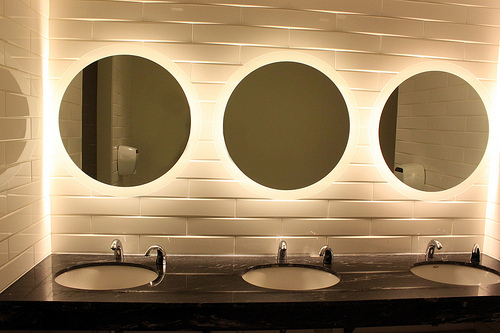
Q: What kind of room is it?
A: It is a bathroom.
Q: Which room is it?
A: It is a bathroom.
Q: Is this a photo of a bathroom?
A: Yes, it is showing a bathroom.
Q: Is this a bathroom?
A: Yes, it is a bathroom.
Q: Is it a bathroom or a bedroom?
A: It is a bathroom.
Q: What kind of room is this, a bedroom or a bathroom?
A: It is a bathroom.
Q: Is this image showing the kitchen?
A: No, the picture is showing the bathroom.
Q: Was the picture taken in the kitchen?
A: No, the picture was taken in the bathroom.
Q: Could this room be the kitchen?
A: No, it is the bathroom.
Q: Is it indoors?
A: Yes, it is indoors.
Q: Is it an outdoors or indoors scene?
A: It is indoors.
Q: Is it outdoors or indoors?
A: It is indoors.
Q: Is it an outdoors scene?
A: No, it is indoors.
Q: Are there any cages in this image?
A: No, there are no cages.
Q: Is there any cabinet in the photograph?
A: No, there are no cabinets.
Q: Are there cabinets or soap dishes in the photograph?
A: No, there are no cabinets or soap dishes.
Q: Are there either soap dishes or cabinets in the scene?
A: No, there are no cabinets or soap dishes.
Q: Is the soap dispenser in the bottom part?
A: Yes, the soap dispenser is in the bottom of the image.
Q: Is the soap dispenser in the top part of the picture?
A: No, the soap dispenser is in the bottom of the image.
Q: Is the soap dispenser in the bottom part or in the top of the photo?
A: The soap dispenser is in the bottom of the image.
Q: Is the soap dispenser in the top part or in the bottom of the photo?
A: The soap dispenser is in the bottom of the image.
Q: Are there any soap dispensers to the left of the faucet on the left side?
A: No, the soap dispenser is to the right of the faucet.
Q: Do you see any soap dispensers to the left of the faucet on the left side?
A: No, the soap dispenser is to the right of the faucet.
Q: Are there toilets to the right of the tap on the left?
A: No, there is a soap dispenser to the right of the faucet.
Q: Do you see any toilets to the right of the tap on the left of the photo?
A: No, there is a soap dispenser to the right of the faucet.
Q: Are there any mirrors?
A: Yes, there is a mirror.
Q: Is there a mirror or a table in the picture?
A: Yes, there is a mirror.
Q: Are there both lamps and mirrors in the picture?
A: No, there is a mirror but no lamps.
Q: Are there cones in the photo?
A: No, there are no cones.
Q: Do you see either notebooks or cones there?
A: No, there are no cones or notebooks.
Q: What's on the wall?
A: The mirror is on the wall.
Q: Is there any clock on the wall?
A: No, there is a mirror on the wall.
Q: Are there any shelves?
A: No, there are no shelves.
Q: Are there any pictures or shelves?
A: No, there are no shelves or pictures.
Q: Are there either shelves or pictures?
A: No, there are no shelves or pictures.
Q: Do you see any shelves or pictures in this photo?
A: No, there are no shelves or pictures.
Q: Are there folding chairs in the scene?
A: No, there are no folding chairs.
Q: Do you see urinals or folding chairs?
A: No, there are no folding chairs or urinals.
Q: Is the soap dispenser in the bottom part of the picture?
A: Yes, the soap dispenser is in the bottom of the image.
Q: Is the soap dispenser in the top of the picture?
A: No, the soap dispenser is in the bottom of the image.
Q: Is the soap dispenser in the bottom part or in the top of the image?
A: The soap dispenser is in the bottom of the image.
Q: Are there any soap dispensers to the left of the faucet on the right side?
A: Yes, there is a soap dispenser to the left of the tap.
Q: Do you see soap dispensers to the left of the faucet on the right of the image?
A: Yes, there is a soap dispenser to the left of the tap.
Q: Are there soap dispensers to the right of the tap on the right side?
A: No, the soap dispenser is to the left of the faucet.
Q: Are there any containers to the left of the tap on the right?
A: No, there is a soap dispenser to the left of the faucet.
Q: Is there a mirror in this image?
A: Yes, there is a mirror.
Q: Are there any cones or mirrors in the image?
A: Yes, there is a mirror.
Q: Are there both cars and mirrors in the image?
A: No, there is a mirror but no cars.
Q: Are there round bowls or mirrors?
A: Yes, there is a round mirror.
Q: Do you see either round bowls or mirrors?
A: Yes, there is a round mirror.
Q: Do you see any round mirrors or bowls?
A: Yes, there is a round mirror.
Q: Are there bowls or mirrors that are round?
A: Yes, the mirror is round.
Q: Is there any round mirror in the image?
A: Yes, there is a round mirror.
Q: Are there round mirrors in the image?
A: Yes, there is a round mirror.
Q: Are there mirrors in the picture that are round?
A: Yes, there is a mirror that is round.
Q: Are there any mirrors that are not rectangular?
A: Yes, there is a round mirror.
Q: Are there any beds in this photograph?
A: No, there are no beds.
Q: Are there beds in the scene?
A: No, there are no beds.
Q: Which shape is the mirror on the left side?
A: The mirror is round.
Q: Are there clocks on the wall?
A: No, there is a mirror on the wall.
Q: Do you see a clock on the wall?
A: No, there is a mirror on the wall.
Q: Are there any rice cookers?
A: No, there are no rice cookers.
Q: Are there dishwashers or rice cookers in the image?
A: No, there are no rice cookers or dishwashers.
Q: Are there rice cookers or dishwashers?
A: No, there are no rice cookers or dishwashers.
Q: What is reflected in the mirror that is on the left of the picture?
A: The hand dryer is reflected in the mirror.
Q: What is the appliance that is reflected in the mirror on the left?
A: The appliance is a hand dryer.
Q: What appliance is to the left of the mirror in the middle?
A: The appliance is a hand dryer.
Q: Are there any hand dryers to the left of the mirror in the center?
A: Yes, there is a hand dryer to the left of the mirror.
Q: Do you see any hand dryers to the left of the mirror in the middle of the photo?
A: Yes, there is a hand dryer to the left of the mirror.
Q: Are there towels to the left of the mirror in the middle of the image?
A: No, there is a hand dryer to the left of the mirror.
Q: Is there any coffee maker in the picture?
A: No, there are no coffee makers.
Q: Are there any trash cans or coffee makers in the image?
A: No, there are no coffee makers or trash cans.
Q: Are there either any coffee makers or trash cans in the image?
A: No, there are no coffee makers or trash cans.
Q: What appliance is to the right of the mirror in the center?
A: The appliance is a hand dryer.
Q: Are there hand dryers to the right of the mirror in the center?
A: Yes, there is a hand dryer to the right of the mirror.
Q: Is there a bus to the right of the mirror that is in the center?
A: No, there is a hand dryer to the right of the mirror.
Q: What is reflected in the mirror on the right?
A: The hand dryer is reflected in the mirror.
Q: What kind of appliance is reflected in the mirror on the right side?
A: The appliance is a hand dryer.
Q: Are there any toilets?
A: No, there are no toilets.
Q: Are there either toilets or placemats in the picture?
A: No, there are no toilets or placemats.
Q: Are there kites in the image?
A: No, there are no kites.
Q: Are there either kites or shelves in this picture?
A: No, there are no kites or shelves.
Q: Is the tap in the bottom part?
A: Yes, the tap is in the bottom of the image.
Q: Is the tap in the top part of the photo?
A: No, the tap is in the bottom of the image.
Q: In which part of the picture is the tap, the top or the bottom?
A: The tap is in the bottom of the image.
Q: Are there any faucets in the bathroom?
A: Yes, there is a faucet in the bathroom.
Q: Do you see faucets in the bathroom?
A: Yes, there is a faucet in the bathroom.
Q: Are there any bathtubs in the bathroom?
A: No, there is a faucet in the bathroom.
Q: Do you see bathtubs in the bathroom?
A: No, there is a faucet in the bathroom.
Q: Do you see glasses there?
A: No, there are no glasses.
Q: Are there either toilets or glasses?
A: No, there are no glasses or toilets.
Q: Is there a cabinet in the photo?
A: No, there are no cabinets.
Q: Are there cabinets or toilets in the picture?
A: No, there are no cabinets or toilets.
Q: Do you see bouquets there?
A: No, there are no bouquets.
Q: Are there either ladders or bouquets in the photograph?
A: No, there are no bouquets or ladders.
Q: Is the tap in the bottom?
A: Yes, the tap is in the bottom of the image.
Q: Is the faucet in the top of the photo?
A: No, the faucet is in the bottom of the image.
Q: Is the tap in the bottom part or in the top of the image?
A: The tap is in the bottom of the image.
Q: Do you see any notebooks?
A: No, there are no notebooks.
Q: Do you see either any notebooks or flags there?
A: No, there are no notebooks or flags.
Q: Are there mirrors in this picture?
A: Yes, there is a mirror.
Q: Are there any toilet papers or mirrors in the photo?
A: Yes, there is a mirror.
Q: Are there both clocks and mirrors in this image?
A: No, there is a mirror but no clocks.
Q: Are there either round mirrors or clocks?
A: Yes, there is a round mirror.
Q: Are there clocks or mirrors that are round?
A: Yes, the mirror is round.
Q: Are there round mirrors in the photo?
A: Yes, there is a round mirror.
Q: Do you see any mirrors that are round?
A: Yes, there is a round mirror.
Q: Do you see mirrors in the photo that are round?
A: Yes, there is a mirror that is round.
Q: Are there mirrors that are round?
A: Yes, there is a mirror that is round.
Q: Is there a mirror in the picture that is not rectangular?
A: Yes, there is a round mirror.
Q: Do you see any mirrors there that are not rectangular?
A: Yes, there is a round mirror.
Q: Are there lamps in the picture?
A: No, there are no lamps.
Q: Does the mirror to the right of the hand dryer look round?
A: Yes, the mirror is round.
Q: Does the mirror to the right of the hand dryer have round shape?
A: Yes, the mirror is round.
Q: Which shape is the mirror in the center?
A: The mirror is round.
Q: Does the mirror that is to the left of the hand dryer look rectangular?
A: No, the mirror is round.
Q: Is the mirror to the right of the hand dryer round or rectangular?
A: The mirror is round.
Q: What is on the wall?
A: The mirror is on the wall.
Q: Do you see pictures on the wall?
A: No, there is a mirror on the wall.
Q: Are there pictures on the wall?
A: No, there is a mirror on the wall.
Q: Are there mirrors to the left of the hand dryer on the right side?
A: Yes, there is a mirror to the left of the hand dryer.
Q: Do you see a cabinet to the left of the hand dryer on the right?
A: No, there is a mirror to the left of the hand dryer.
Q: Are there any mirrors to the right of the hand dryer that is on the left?
A: Yes, there is a mirror to the right of the hand dryer.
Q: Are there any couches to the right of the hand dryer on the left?
A: No, there is a mirror to the right of the hand dryer.